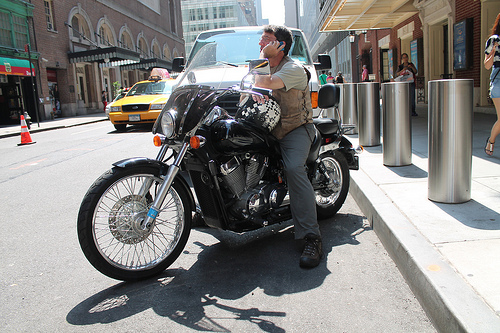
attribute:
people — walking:
[322, 40, 499, 93]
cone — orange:
[16, 112, 36, 146]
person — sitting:
[245, 5, 335, 280]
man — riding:
[248, 26, 308, 108]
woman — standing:
[395, 51, 413, 76]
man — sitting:
[73, 22, 362, 285]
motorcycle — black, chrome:
[75, 73, 384, 286]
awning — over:
[67, 40, 142, 67]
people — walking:
[317, 0, 499, 160]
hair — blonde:
[484, 10, 499, 43]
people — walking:
[352, 48, 429, 125]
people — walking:
[317, 51, 424, 106]